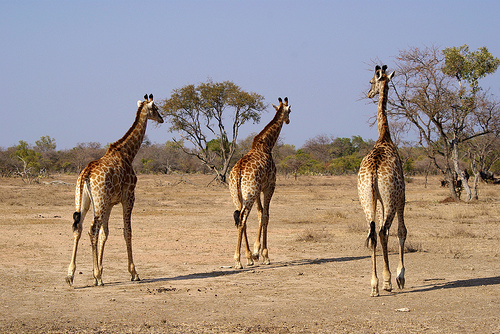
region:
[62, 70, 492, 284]
Three giraffes.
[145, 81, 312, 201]
Tree with green leaves.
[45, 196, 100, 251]
Black tail on the giraffe.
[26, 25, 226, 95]
Blue sky over the trees.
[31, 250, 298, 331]
Dirt under giraffes feet.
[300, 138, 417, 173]
Green bushes behind the field.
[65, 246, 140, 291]
Four giraffe feet.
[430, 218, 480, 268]
Shrub on dirt field.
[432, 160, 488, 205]
Base of a tree.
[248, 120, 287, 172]
Mane on the middle giraffe.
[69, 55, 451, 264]
three giraffes in a row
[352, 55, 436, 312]
tallest giraffe on right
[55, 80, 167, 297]
giraffe on left side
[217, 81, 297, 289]
giraffe in middle of group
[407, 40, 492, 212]
dead tree with little green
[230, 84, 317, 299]
middle giraffe walking straight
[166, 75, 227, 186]
tall bonsai like tree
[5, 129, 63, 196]
small shrub like tree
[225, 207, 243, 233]
tuft of black hair on tail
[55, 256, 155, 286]
four hooves on feet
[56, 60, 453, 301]
giraffes moving farther away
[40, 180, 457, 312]
ground of flattened dirt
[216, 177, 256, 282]
rear legs crossed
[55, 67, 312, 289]
giraffes with necks leaning forward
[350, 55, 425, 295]
giraffe standing upright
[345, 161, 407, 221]
faded markings across thighs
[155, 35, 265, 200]
individual tree with leaves on ends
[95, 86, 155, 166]
thick and dark mane running down neck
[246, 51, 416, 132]
head turned to look at lead giraffe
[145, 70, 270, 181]
tree growing in fan shape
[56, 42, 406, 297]
three giraffes walking in field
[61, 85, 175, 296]
brown and white giraffe walking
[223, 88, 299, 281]
brown and white giraffe walking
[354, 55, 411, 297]
brown and white giraffe walking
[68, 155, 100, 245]
giraffe tail with bushy black end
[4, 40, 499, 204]
green trees in background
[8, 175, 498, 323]
brown dirt field in bush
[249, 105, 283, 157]
long dark mane on giraffe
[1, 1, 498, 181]
clear blue cloudless sky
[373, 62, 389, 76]
two horns on giraffe head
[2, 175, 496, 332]
Dry brown ground surface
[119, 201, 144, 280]
Right front leg of the giraffe on the left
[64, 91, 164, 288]
Entire first giraffe on the left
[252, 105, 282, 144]
Mane on the giraffe in the middle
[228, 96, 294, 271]
Entire giraffe in the middle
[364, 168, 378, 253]
Tail on the giraffe on the right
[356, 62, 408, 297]
Entire giraffe on the right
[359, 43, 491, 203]
Largest sigle tree in the scene on the right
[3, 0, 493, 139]
Grayish blue sky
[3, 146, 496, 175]
Thicket of trees at the end of the brown dry ground